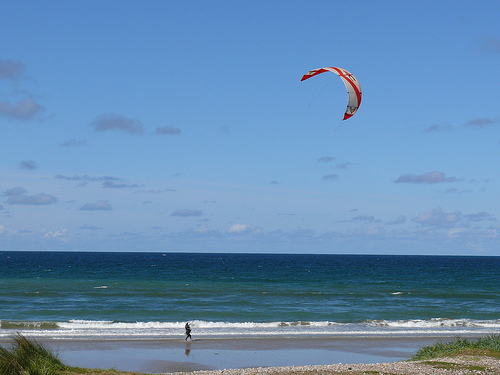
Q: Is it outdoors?
A: Yes, it is outdoors.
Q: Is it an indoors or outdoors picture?
A: It is outdoors.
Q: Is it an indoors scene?
A: No, it is outdoors.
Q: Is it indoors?
A: No, it is outdoors.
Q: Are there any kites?
A: Yes, there is a kite.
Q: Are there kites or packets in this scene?
A: Yes, there is a kite.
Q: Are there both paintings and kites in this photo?
A: No, there is a kite but no paintings.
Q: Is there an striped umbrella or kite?
A: Yes, there is a striped kite.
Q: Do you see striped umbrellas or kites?
A: Yes, there is a striped kite.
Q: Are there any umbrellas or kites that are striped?
A: Yes, the kite is striped.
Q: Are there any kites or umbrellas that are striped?
A: Yes, the kite is striped.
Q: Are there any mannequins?
A: No, there are no mannequins.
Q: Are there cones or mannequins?
A: No, there are no mannequins or cones.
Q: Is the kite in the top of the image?
A: Yes, the kite is in the top of the image.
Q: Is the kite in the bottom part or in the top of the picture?
A: The kite is in the top of the image.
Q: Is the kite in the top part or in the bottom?
A: The kite is in the top of the image.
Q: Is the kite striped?
A: Yes, the kite is striped.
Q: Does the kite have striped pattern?
A: Yes, the kite is striped.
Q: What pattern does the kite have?
A: The kite has striped pattern.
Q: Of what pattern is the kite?
A: The kite is striped.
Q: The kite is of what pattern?
A: The kite is striped.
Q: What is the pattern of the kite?
A: The kite is striped.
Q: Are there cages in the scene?
A: No, there are no cages.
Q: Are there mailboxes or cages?
A: No, there are no cages or mailboxes.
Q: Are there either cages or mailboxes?
A: No, there are no cages or mailboxes.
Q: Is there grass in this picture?
A: Yes, there is grass.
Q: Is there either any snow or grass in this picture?
A: Yes, there is grass.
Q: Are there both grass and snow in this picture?
A: No, there is grass but no snow.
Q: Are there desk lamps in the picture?
A: No, there are no desk lamps.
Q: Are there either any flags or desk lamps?
A: No, there are no desk lamps or flags.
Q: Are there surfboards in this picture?
A: No, there are no surfboards.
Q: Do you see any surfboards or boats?
A: No, there are no surfboards or boats.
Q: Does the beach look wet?
A: Yes, the beach is wet.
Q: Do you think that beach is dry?
A: No, the beach is wet.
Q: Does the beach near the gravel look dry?
A: No, the beach is wet.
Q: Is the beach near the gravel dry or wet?
A: The beach is wet.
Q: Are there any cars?
A: No, there are no cars.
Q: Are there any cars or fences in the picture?
A: No, there are no cars or fences.